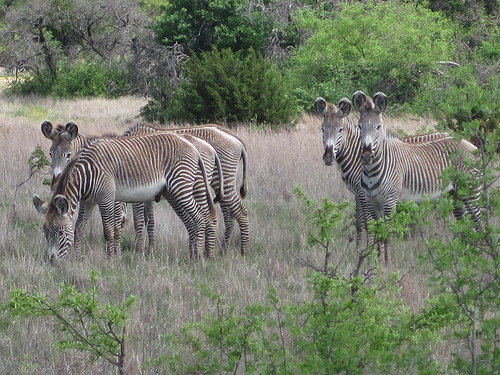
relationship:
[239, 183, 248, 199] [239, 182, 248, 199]
tip belonging to tail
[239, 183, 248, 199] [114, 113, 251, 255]
tip belonging to zebra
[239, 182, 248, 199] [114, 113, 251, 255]
tail belonging to zebra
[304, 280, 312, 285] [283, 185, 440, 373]
leaf growing on bush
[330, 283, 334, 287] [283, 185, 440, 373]
leaf growing on bush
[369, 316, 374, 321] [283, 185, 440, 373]
leaf growing on bush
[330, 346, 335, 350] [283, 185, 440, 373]
leaf growing on bush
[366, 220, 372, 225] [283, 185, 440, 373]
leaf growing on bush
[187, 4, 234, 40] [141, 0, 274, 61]
green leaves on a tree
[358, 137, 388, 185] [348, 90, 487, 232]
neck on zebra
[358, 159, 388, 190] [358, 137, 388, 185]
stripe pattern on neck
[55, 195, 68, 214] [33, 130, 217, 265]
ear of zebra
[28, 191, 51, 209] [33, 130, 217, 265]
ear of zebra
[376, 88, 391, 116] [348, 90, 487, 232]
ear of zebra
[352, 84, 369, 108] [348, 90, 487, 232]
ear of zebra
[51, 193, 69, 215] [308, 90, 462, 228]
ear of zebra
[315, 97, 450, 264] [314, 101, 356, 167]
zebra has muzzle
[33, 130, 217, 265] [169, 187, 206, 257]
zebra has legs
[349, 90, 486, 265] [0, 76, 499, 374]
zebra in field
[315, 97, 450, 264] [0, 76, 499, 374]
zebra in field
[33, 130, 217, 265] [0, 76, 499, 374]
zebra in field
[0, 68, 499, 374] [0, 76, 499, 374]
dry grass in field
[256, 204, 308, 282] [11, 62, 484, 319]
dry grass in field